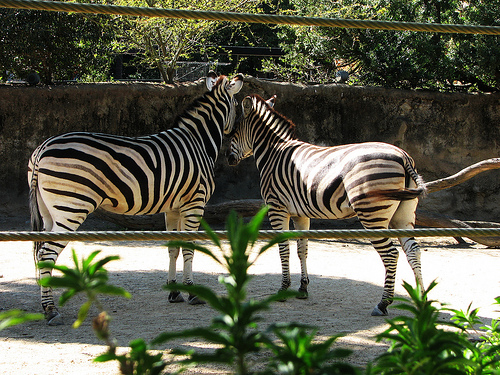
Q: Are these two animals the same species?
A: Yes, all the animals are zebras.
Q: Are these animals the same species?
A: Yes, all the animals are zebras.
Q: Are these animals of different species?
A: No, all the animals are zebras.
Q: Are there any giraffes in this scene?
A: No, there are no giraffes.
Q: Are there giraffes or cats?
A: No, there are no giraffes or cats.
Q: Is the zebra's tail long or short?
A: The tail is long.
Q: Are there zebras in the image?
A: Yes, there is a zebra.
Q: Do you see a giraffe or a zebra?
A: Yes, there is a zebra.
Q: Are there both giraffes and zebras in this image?
A: No, there is a zebra but no giraffes.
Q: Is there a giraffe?
A: No, there are no giraffes.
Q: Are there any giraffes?
A: No, there are no giraffes.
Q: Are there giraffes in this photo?
A: No, there are no giraffes.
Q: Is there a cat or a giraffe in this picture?
A: No, there are no giraffes or cats.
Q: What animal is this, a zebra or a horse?
A: This is a zebra.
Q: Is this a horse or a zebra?
A: This is a zebra.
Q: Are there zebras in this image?
A: Yes, there is a zebra.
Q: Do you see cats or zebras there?
A: Yes, there is a zebra.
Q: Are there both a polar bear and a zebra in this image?
A: No, there is a zebra but no polar bears.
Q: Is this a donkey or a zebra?
A: This is a zebra.